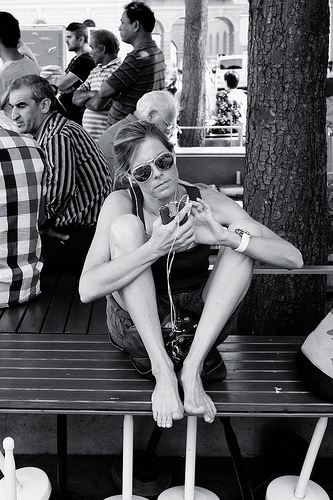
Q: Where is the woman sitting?
A: Bench.